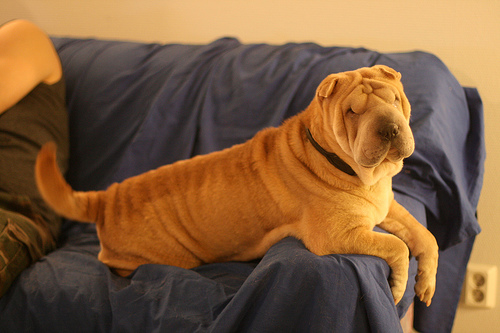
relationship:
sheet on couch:
[0, 36, 478, 331] [66, 23, 323, 95]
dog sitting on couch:
[32, 65, 440, 307] [0, 29, 485, 331]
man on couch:
[0, 16, 68, 293] [0, 29, 485, 331]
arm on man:
[1, 17, 53, 114] [0, 16, 68, 293]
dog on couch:
[32, 65, 440, 307] [0, 29, 485, 331]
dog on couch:
[40, 36, 468, 313] [0, 29, 485, 331]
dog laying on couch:
[32, 65, 440, 307] [49, 37, 462, 188]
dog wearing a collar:
[32, 65, 440, 307] [300, 117, 359, 184]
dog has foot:
[32, 65, 440, 307] [362, 225, 412, 307]